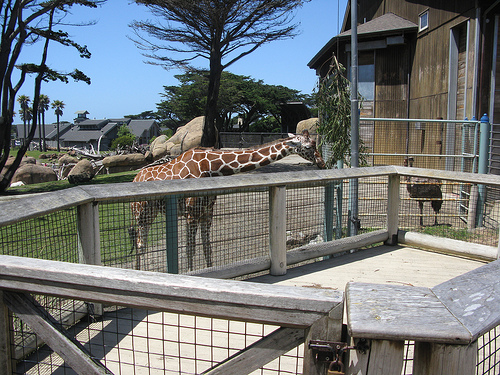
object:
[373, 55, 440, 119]
wall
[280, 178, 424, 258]
fence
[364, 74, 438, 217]
gate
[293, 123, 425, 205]
gate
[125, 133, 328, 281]
giraffe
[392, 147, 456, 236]
bird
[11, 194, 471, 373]
pen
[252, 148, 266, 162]
spot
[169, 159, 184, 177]
spot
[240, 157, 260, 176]
spot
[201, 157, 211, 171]
spot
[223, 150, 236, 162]
spot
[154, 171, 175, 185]
spot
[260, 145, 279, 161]
spot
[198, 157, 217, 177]
spot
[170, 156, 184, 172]
spot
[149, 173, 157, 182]
spot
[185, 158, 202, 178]
spot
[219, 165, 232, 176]
spot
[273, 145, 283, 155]
spot